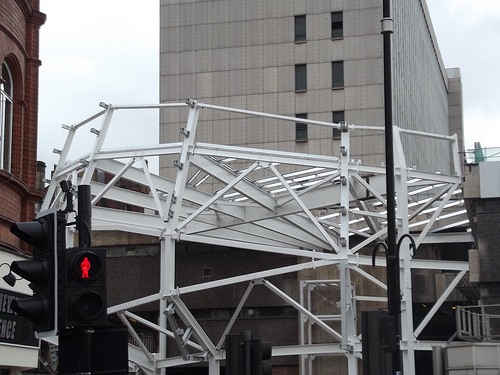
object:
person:
[79, 255, 93, 278]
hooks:
[370, 240, 391, 272]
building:
[156, 0, 461, 258]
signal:
[69, 249, 104, 288]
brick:
[10, 137, 25, 141]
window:
[0, 93, 15, 173]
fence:
[463, 140, 500, 163]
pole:
[381, 20, 407, 332]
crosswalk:
[28, 174, 195, 374]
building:
[0, 0, 60, 374]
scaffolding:
[31, 99, 500, 374]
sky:
[38, 0, 500, 178]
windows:
[329, 58, 344, 91]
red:
[79, 260, 90, 274]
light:
[65, 248, 105, 281]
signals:
[9, 219, 52, 247]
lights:
[35, 332, 60, 375]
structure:
[32, 102, 500, 375]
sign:
[8, 295, 46, 323]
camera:
[56, 177, 75, 210]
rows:
[290, 61, 353, 94]